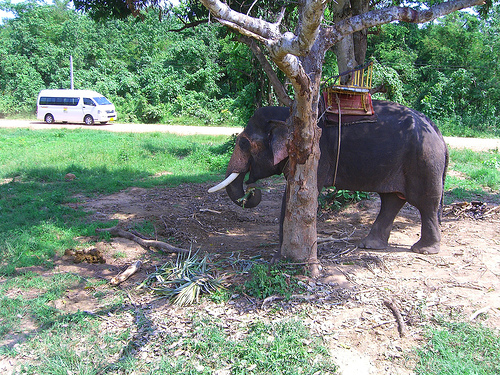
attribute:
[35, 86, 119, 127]
car — white, big, traveling, transporting, small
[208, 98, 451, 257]
elephant — walking, black, big, eating, brow ad grey, small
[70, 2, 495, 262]
tree — in the foreground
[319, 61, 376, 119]
saddle — on top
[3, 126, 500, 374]
grass — green, torn up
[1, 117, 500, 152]
road — sandy, dirt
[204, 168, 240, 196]
tusk — white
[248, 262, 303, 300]
leaves — dropped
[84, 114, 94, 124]
wheel — black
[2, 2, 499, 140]
trees — in background, thick, lush, green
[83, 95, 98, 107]
windows — black